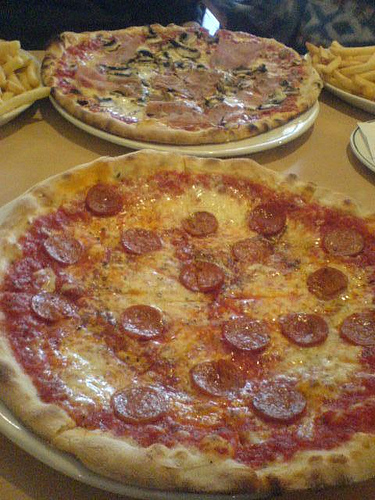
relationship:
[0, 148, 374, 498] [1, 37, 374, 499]
pizza on table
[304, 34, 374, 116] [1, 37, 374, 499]
french fries on table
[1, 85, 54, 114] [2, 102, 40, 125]
fry on plate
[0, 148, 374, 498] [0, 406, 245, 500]
pizza on plate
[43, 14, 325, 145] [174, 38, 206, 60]
pizza with mushrooms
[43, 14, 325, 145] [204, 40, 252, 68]
pizza with ham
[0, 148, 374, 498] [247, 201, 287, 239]
pizza with pepperoni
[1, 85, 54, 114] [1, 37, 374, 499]
fry on table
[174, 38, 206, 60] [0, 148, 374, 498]
mushrooms on pizza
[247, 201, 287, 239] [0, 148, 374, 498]
pepperoni on pizza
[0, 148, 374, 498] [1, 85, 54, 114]
pizza and fry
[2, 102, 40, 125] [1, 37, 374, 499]
plate on table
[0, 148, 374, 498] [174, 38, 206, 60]
pizza with mushrooms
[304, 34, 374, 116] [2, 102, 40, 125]
french fries on plate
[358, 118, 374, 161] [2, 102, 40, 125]
napkin on plate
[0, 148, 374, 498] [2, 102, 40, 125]
pizza on plate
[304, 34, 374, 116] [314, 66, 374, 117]
french fries on plate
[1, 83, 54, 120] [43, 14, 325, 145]
fry touching pizza